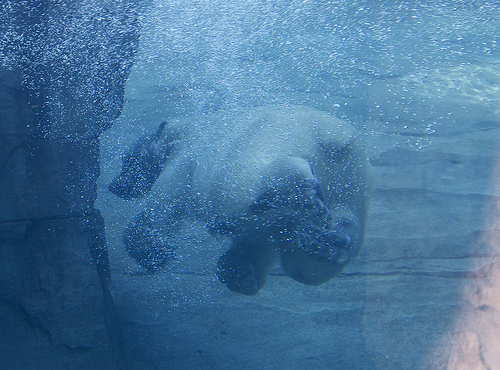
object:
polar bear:
[101, 102, 377, 298]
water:
[2, 0, 497, 369]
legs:
[215, 238, 276, 296]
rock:
[2, 0, 153, 220]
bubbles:
[0, 0, 499, 370]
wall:
[0, 0, 147, 370]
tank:
[0, 3, 498, 370]